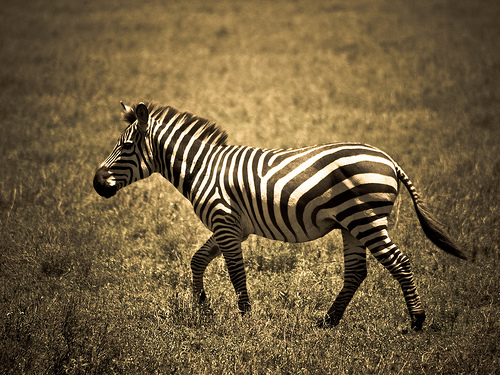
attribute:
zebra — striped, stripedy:
[82, 99, 463, 344]